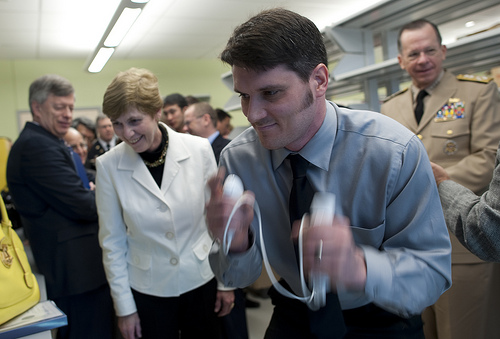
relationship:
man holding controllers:
[206, 7, 459, 334] [223, 172, 345, 309]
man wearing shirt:
[206, 7, 459, 334] [208, 99, 455, 318]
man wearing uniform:
[371, 17, 499, 337] [372, 68, 500, 333]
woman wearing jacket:
[93, 65, 236, 328] [90, 132, 232, 311]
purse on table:
[4, 188, 40, 320] [4, 294, 69, 333]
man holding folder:
[3, 72, 121, 336] [68, 145, 96, 192]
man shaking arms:
[206, 7, 459, 334] [205, 138, 455, 319]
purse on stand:
[4, 188, 40, 320] [4, 294, 69, 333]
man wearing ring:
[206, 7, 459, 334] [312, 243, 322, 262]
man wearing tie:
[206, 7, 459, 334] [285, 153, 315, 284]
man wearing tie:
[371, 17, 499, 337] [411, 87, 433, 123]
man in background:
[3, 72, 121, 336] [1, 1, 498, 322]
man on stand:
[3, 72, 121, 336] [0, 226, 73, 338]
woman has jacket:
[93, 65, 236, 328] [90, 132, 232, 311]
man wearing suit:
[3, 72, 121, 336] [2, 123, 137, 336]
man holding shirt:
[206, 7, 459, 334] [208, 99, 455, 318]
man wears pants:
[3, 72, 121, 336] [56, 282, 124, 338]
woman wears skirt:
[93, 65, 236, 328] [128, 279, 216, 336]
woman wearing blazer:
[93, 65, 236, 328] [90, 132, 232, 311]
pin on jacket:
[454, 110, 471, 123] [374, 68, 500, 268]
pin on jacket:
[456, 71, 494, 84] [374, 68, 500, 268]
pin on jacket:
[445, 95, 464, 104] [90, 132, 232, 311]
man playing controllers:
[206, 7, 459, 334] [223, 172, 345, 309]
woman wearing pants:
[93, 65, 236, 328] [128, 276, 219, 332]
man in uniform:
[371, 17, 499, 337] [372, 68, 500, 333]